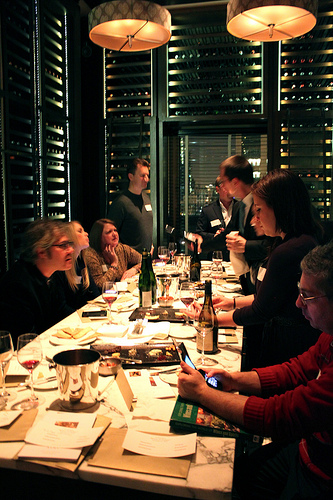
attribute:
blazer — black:
[194, 199, 236, 247]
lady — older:
[89, 219, 141, 285]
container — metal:
[41, 340, 114, 408]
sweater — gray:
[113, 190, 152, 254]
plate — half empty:
[97, 341, 183, 369]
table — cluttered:
[25, 197, 289, 420]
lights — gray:
[89, 7, 318, 78]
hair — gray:
[13, 218, 69, 265]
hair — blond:
[64, 220, 89, 291]